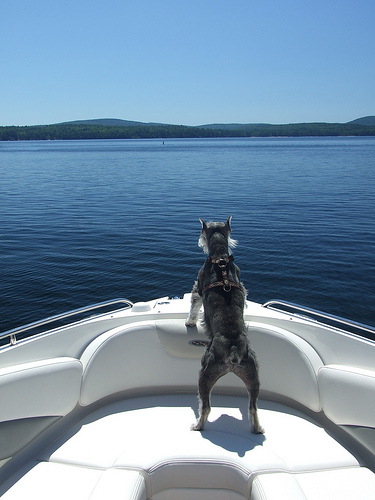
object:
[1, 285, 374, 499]
boat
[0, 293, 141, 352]
silver railing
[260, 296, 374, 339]
silver railing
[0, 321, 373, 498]
white cushions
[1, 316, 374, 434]
back seat cushions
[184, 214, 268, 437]
dog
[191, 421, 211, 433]
gray foot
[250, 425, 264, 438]
gray foot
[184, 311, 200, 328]
gray foot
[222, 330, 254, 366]
gray tail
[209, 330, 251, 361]
gray butt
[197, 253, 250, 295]
brown harness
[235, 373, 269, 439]
back legs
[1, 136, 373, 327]
water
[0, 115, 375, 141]
mountain top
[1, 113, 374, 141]
horizon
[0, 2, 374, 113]
sky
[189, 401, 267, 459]
dog shadow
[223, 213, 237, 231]
pointy ears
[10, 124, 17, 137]
trees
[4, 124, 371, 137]
distance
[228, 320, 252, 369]
clipped tail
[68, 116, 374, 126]
hills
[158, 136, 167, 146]
buoy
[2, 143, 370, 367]
light